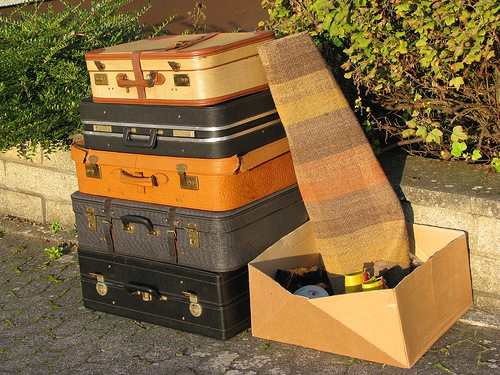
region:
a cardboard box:
[247, 214, 472, 366]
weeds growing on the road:
[43, 218, 66, 261]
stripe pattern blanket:
[256, 33, 407, 270]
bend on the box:
[304, 296, 405, 366]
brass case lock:
[183, 290, 200, 315]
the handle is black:
[121, 283, 164, 301]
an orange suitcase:
[71, 141, 294, 211]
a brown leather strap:
[132, 32, 217, 98]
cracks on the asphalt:
[5, 309, 280, 373]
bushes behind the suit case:
[1, 1, 498, 159]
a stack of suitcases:
[52, 37, 267, 371]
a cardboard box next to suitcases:
[220, 185, 473, 374]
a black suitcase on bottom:
[65, 242, 250, 352]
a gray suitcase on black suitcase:
[74, 196, 244, 280]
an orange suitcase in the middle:
[60, 135, 298, 223]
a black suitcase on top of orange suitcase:
[73, 94, 301, 164]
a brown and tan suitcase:
[74, 32, 276, 118]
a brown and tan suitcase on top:
[77, 23, 272, 105]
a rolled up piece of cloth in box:
[247, 7, 426, 300]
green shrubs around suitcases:
[6, 5, 498, 157]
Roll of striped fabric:
[250, 29, 413, 303]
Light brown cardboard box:
[247, 214, 472, 371]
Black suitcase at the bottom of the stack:
[77, 247, 254, 347]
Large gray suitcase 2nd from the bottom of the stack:
[67, 187, 309, 273]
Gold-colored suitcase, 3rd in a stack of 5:
[67, 144, 299, 214]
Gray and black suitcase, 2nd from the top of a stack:
[77, 97, 290, 159]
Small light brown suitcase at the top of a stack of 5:
[85, 32, 277, 109]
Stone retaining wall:
[0, 104, 499, 339]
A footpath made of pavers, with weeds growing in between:
[0, 211, 496, 373]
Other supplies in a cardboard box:
[272, 244, 428, 305]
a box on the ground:
[243, 204, 478, 346]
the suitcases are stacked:
[51, 3, 281, 353]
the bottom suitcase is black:
[27, 234, 238, 346]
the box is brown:
[242, 212, 470, 352]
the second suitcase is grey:
[50, 186, 245, 274]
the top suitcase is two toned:
[54, 2, 290, 97]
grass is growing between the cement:
[7, 210, 72, 320]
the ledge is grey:
[382, 145, 489, 222]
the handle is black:
[103, 200, 165, 246]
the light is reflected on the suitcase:
[187, 114, 242, 158]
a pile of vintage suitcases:
[65, 28, 317, 345]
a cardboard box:
[244, 218, 476, 368]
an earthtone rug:
[256, 30, 418, 294]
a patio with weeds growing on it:
[0, 215, 496, 374]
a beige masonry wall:
[0, 143, 499, 323]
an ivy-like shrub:
[258, 0, 498, 178]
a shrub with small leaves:
[1, 0, 198, 154]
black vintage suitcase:
[73, 248, 291, 343]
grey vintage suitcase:
[67, 182, 313, 274]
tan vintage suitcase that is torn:
[72, 136, 302, 213]